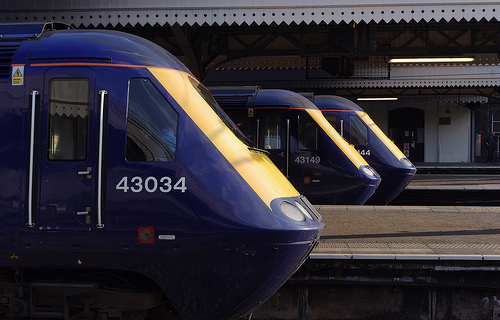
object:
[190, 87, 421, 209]
train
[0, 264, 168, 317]
engine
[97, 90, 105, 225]
bar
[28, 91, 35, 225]
bar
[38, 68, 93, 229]
door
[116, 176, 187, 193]
numbering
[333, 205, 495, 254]
platform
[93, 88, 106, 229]
handle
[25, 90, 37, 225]
handle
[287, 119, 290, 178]
handle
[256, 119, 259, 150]
handle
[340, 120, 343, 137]
handle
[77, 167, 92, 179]
door handle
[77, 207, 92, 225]
door handle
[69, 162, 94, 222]
pair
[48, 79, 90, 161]
window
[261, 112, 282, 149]
window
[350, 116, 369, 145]
window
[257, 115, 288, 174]
door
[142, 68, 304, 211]
sticker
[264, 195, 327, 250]
nose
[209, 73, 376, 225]
train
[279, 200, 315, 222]
light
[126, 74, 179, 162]
window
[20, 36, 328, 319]
cockpit